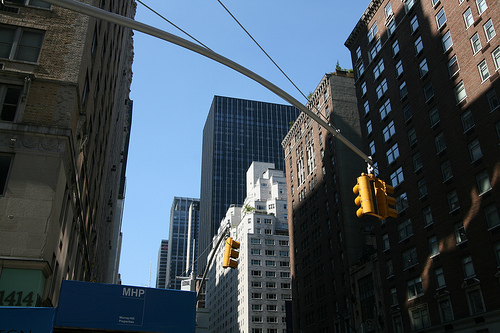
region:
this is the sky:
[137, 89, 177, 182]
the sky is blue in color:
[148, 97, 176, 165]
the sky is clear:
[138, 128, 158, 197]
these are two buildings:
[306, 29, 460, 330]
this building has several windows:
[365, 35, 424, 128]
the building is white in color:
[235, 270, 253, 312]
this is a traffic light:
[352, 161, 396, 223]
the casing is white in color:
[359, 180, 370, 205]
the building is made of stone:
[55, 21, 65, 72]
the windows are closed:
[383, 123, 398, 160]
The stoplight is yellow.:
[333, 161, 415, 216]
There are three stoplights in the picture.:
[193, 153, 431, 273]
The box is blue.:
[55, 267, 204, 330]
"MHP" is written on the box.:
[111, 278, 171, 305]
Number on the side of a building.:
[3, 265, 50, 320]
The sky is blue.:
[148, 55, 202, 125]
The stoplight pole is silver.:
[100, 5, 312, 79]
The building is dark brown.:
[406, 37, 498, 147]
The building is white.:
[241, 251, 291, 316]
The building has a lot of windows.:
[217, 105, 279, 162]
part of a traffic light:
[353, 190, 401, 228]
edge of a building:
[242, 257, 251, 304]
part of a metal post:
[293, 108, 359, 168]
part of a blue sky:
[141, 110, 182, 175]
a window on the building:
[376, 100, 391, 115]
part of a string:
[273, 60, 315, 100]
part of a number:
[8, 290, 35, 300]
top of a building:
[354, 7, 380, 44]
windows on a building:
[252, 238, 284, 318]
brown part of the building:
[451, 31, 476, 62]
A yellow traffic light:
[349, 171, 400, 223]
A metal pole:
[103, 15, 378, 172]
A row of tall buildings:
[175, 73, 482, 315]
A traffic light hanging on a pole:
[110, 3, 390, 231]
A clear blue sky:
[142, 68, 198, 197]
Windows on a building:
[365, 39, 487, 155]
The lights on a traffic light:
[227, 238, 239, 272]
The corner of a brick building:
[12, 37, 107, 250]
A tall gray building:
[190, 91, 275, 222]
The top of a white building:
[207, 161, 288, 238]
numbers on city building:
[1, 282, 41, 309]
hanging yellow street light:
[349, 160, 401, 228]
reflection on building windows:
[364, 59, 401, 146]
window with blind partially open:
[474, 58, 491, 88]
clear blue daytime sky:
[160, 57, 198, 117]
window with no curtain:
[264, 286, 278, 305]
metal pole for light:
[180, 34, 250, 75]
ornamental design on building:
[19, 134, 65, 160]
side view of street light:
[218, 231, 246, 278]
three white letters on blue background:
[116, 283, 151, 305]